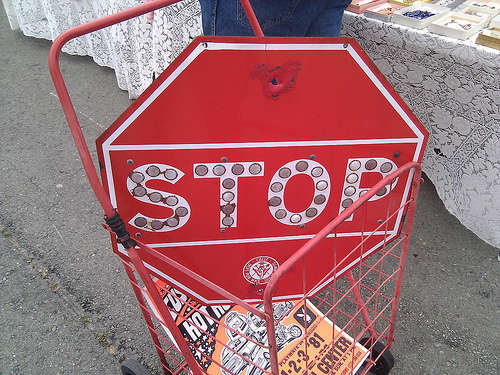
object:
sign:
[93, 36, 430, 306]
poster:
[141, 277, 371, 374]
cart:
[47, 0, 430, 374]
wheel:
[359, 337, 395, 374]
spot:
[145, 165, 161, 177]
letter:
[126, 163, 191, 232]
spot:
[132, 186, 146, 197]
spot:
[166, 196, 178, 206]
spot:
[134, 217, 147, 227]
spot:
[151, 220, 163, 230]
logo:
[242, 256, 280, 285]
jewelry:
[346, 0, 500, 50]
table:
[340, 1, 499, 249]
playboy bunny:
[293, 303, 317, 328]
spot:
[270, 182, 283, 193]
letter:
[267, 158, 331, 225]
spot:
[289, 214, 302, 223]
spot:
[314, 194, 327, 205]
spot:
[317, 180, 329, 191]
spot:
[297, 159, 308, 172]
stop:
[126, 157, 399, 232]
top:
[96, 38, 427, 146]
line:
[109, 138, 419, 151]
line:
[134, 231, 394, 249]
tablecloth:
[0, 0, 499, 249]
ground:
[0, 14, 499, 373]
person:
[200, 1, 353, 40]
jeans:
[198, 0, 353, 36]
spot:
[212, 163, 226, 175]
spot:
[345, 172, 358, 184]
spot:
[267, 196, 282, 206]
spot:
[380, 161, 393, 173]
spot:
[223, 216, 234, 226]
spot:
[194, 165, 208, 176]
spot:
[248, 163, 262, 176]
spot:
[278, 167, 291, 179]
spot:
[311, 166, 324, 178]